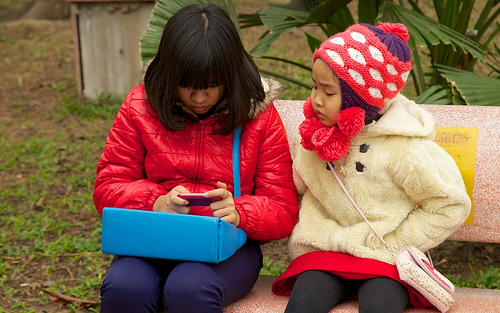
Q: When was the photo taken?
A: Daytime.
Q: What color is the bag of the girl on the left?
A: Blue.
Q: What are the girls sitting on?
A: Bench.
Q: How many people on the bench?
A: Two.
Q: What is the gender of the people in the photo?
A: Female.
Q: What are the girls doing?
A: Sitting.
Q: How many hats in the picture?
A: One.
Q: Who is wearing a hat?
A: Girl.